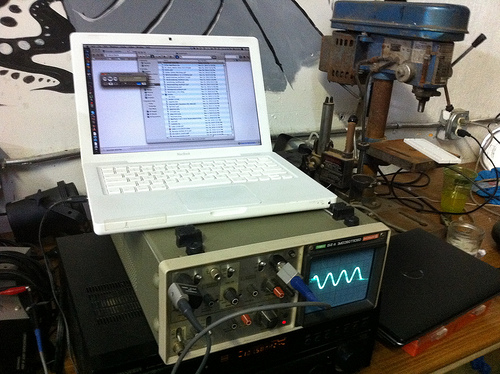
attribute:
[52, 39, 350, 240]
macbook — white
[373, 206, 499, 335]
laptop — closed, black, white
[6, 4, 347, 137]
wall — white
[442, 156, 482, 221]
glass — yellow, plastic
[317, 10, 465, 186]
tool — blue, rusted, metal, large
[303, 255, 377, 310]
screen — small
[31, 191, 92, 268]
cord — black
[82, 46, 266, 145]
computer screen — on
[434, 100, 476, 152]
outlet — electrical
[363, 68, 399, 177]
drill press — rusty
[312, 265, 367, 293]
lines — green, wavy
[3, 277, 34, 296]
clip — red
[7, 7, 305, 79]
designs — painted, wavy, black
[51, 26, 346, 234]
laptop — open, white, on, computer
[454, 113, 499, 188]
cords — electrical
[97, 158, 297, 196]
keyboard — white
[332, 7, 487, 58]
machine — drilling, blue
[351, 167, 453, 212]
plugs — plugged